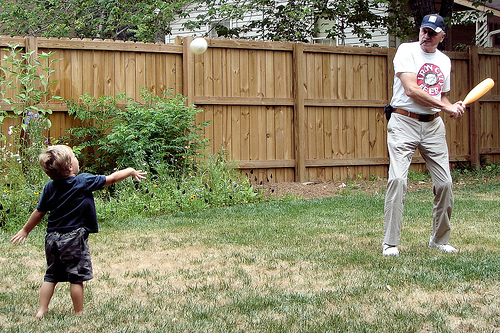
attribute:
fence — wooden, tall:
[0, 30, 389, 165]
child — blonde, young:
[5, 135, 153, 321]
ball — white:
[183, 32, 212, 60]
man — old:
[371, 7, 494, 260]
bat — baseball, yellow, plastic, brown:
[459, 73, 497, 110]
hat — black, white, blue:
[420, 10, 448, 38]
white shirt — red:
[386, 41, 453, 117]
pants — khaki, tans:
[379, 112, 457, 251]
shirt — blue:
[33, 172, 113, 234]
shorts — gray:
[38, 229, 97, 283]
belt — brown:
[389, 106, 444, 123]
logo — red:
[415, 62, 449, 97]